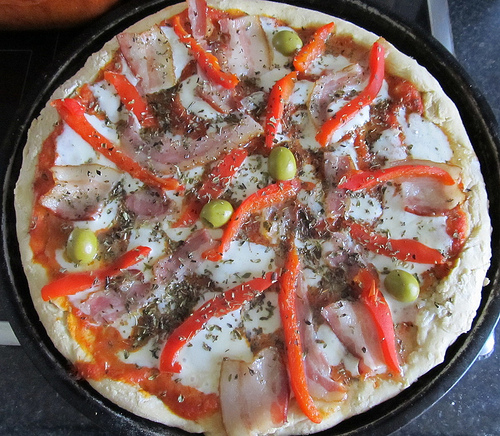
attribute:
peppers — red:
[262, 249, 352, 408]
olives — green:
[194, 199, 240, 223]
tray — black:
[396, 380, 451, 413]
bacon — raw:
[225, 363, 295, 414]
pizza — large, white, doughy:
[72, 169, 399, 364]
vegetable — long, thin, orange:
[257, 250, 334, 423]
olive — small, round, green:
[65, 230, 107, 270]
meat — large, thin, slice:
[193, 367, 303, 418]